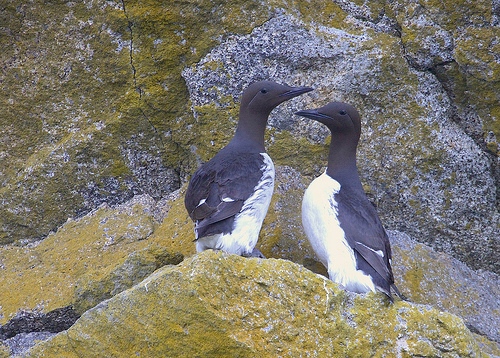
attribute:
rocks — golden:
[18, 247, 485, 354]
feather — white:
[211, 147, 257, 205]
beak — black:
[294, 100, 323, 128]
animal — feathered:
[198, 61, 305, 263]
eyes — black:
[262, 87, 269, 95]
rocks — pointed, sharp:
[3, 1, 498, 353]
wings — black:
[338, 189, 401, 295]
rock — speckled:
[169, 6, 497, 271]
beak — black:
[294, 104, 325, 121]